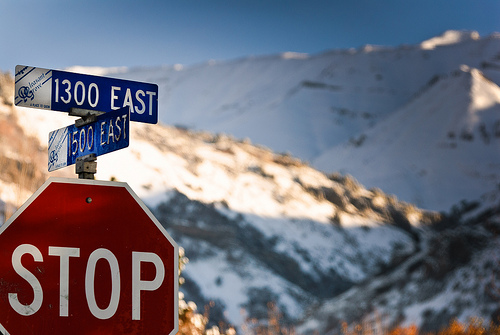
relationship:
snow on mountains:
[21, 36, 498, 217] [0, 30, 500, 333]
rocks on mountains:
[290, 169, 442, 238] [0, 30, 500, 333]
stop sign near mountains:
[0, 177, 180, 333] [0, 30, 500, 333]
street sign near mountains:
[47, 104, 129, 172] [0, 30, 500, 333]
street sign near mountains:
[15, 64, 157, 117] [0, 30, 500, 333]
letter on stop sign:
[7, 243, 44, 317] [0, 177, 180, 333]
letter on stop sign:
[48, 245, 82, 318] [0, 177, 180, 333]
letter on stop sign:
[84, 246, 121, 320] [0, 177, 180, 333]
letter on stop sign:
[131, 251, 165, 323] [0, 177, 180, 333]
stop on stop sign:
[7, 242, 164, 319] [0, 177, 180, 333]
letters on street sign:
[52, 78, 157, 117] [15, 64, 157, 117]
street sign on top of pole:
[15, 64, 157, 117] [76, 110, 97, 182]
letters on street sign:
[66, 112, 130, 156] [47, 104, 129, 172]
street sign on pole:
[47, 104, 129, 172] [76, 110, 97, 182]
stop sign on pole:
[0, 177, 180, 333] [76, 110, 97, 182]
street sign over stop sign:
[47, 104, 129, 172] [0, 177, 180, 333]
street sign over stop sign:
[15, 64, 157, 117] [0, 177, 180, 333]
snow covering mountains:
[21, 36, 498, 217] [0, 30, 500, 333]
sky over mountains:
[1, 1, 499, 73] [0, 30, 500, 333]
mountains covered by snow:
[0, 30, 500, 333] [21, 36, 498, 217]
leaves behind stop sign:
[176, 246, 500, 334] [0, 177, 180, 333]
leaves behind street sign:
[176, 246, 500, 334] [47, 104, 129, 172]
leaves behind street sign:
[176, 246, 500, 334] [15, 64, 157, 117]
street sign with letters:
[47, 104, 129, 172] [66, 112, 130, 156]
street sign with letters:
[15, 64, 157, 117] [52, 78, 157, 117]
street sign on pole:
[15, 64, 157, 117] [76, 110, 97, 182]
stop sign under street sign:
[0, 177, 180, 333] [47, 104, 129, 172]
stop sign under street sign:
[0, 177, 180, 333] [15, 64, 157, 117]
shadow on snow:
[143, 193, 497, 321] [21, 36, 498, 217]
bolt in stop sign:
[85, 197, 94, 204] [0, 177, 180, 333]